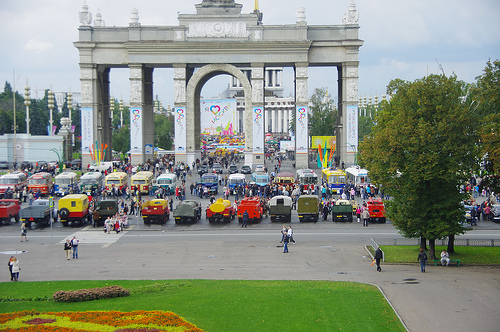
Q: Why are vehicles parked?
A: Not in use.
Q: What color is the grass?
A: Green.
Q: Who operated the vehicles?
A: Drivers.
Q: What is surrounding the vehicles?
A: People.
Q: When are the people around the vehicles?
A: Daytime.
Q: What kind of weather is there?
A: Overcast.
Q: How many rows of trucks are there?
A: Two.